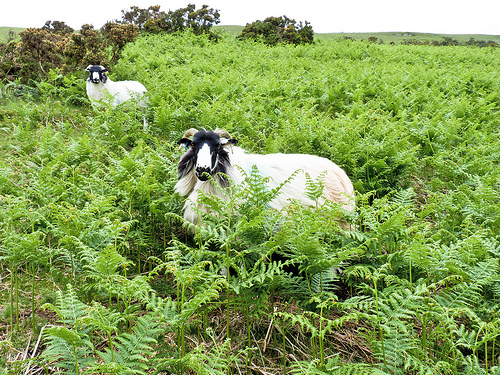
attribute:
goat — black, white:
[205, 127, 350, 234]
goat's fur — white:
[241, 151, 326, 191]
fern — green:
[109, 161, 140, 191]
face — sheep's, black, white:
[89, 64, 110, 85]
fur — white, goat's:
[173, 127, 356, 230]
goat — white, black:
[80, 66, 145, 116]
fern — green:
[409, 234, 466, 279]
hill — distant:
[319, 29, 495, 39]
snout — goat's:
[193, 160, 214, 187]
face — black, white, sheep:
[187, 130, 222, 182]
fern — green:
[440, 229, 487, 270]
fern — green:
[439, 314, 476, 355]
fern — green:
[227, 251, 304, 294]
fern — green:
[50, 281, 90, 331]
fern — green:
[197, 337, 237, 372]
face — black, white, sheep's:
[81, 64, 108, 81]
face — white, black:
[180, 119, 232, 182]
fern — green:
[407, 240, 467, 295]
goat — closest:
[170, 126, 355, 248]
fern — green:
[7, 35, 497, 373]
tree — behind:
[110, 4, 226, 43]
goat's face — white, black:
[188, 132, 222, 182]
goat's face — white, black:
[86, 64, 103, 84]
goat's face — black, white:
[190, 130, 219, 179]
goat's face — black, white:
[88, 64, 102, 84]